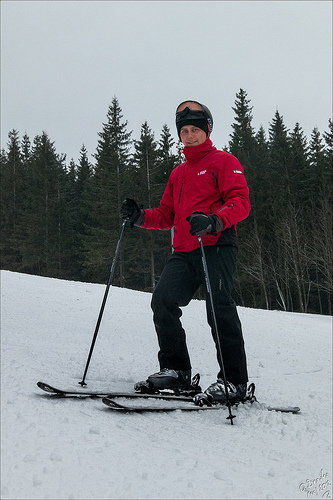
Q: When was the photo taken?
A: Daytime.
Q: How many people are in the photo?
A: One.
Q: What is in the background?
A: Trees.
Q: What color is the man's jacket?
A: Red.